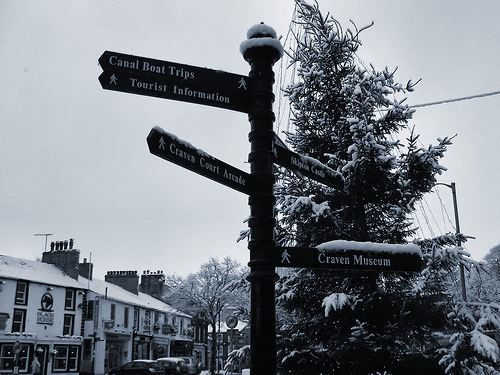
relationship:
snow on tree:
[250, 10, 493, 370] [248, 0, 460, 351]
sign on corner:
[95, 49, 243, 116] [10, 15, 499, 356]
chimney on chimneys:
[35, 222, 100, 294] [39, 237, 167, 299]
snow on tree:
[221, 2, 495, 372] [263, 21, 480, 361]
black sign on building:
[36, 292, 57, 331] [1, 253, 102, 373]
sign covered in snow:
[274, 247, 426, 274] [315, 240, 422, 260]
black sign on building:
[35, 296, 57, 326] [1, 241, 93, 367]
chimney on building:
[42, 227, 88, 272] [19, 256, 191, 356]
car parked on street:
[115, 357, 170, 374] [123, 360, 259, 373]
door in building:
[32, 343, 49, 373] [0, 255, 94, 374]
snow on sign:
[330, 235, 422, 250] [273, 245, 426, 274]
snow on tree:
[315, 238, 423, 253] [248, 0, 473, 362]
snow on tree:
[444, 245, 471, 257] [248, 0, 473, 362]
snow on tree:
[347, 145, 357, 168] [248, 0, 473, 362]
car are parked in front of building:
[115, 357, 170, 374] [0, 243, 203, 371]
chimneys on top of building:
[32, 227, 172, 294] [0, 280, 200, 370]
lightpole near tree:
[419, 183, 481, 303] [250, 4, 484, 372]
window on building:
[10, 280, 31, 305] [0, 243, 203, 371]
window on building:
[6, 308, 27, 335] [0, 243, 203, 371]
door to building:
[33, 345, 48, 374] [1, 237, 80, 373]